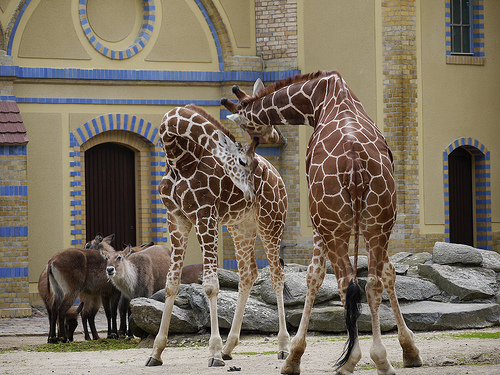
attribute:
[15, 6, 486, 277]
house — large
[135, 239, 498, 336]
rocks — large, gray, Very big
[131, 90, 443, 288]
graiffe — bended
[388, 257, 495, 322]
rocks — large, gray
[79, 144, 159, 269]
doorway — arched, yellow, blue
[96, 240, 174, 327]
gray mule — bunch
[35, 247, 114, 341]
gray mule — bunch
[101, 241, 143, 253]
gray mule — bunch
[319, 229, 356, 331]
leg — brown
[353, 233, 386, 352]
leg — brown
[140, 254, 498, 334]
rocks — gray, large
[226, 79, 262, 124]
ears — light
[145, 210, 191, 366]
leg — white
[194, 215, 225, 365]
leg — white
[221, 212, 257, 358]
leg — white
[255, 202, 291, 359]
leg — white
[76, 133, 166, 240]
door — arched, yellow, blue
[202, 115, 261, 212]
head — turned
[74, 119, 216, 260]
door — blue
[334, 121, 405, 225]
spots — white, brown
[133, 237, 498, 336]
rock pile — grey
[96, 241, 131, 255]
ears — furry, little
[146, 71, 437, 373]
two giraffes — bended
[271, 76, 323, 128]
neck — giraffe's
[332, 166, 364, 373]
tail — black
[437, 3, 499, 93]
window — yellow, blue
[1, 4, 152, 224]
yellow building — big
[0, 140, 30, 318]
wall — brick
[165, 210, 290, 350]
legs — four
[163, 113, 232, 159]
neck — long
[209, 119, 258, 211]
head — turned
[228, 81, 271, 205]
head — down